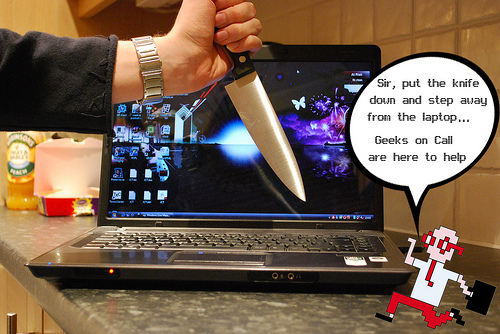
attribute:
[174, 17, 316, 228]
knife — silver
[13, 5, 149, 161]
sleeve — black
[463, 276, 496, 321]
suit case — small, black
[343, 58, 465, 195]
quote — cartoon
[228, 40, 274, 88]
bolt — small, silver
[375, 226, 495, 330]
character — cartoon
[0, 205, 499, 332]
counter top — black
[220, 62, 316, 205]
blade — sharp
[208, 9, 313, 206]
knife — old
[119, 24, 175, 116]
band — silver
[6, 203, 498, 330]
tabletop — gray, stone